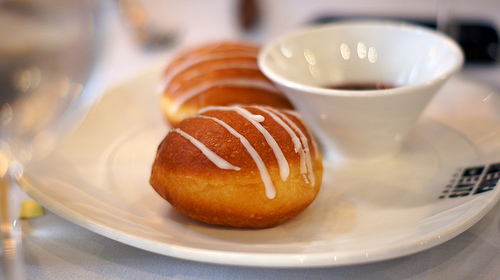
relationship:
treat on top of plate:
[147, 103, 324, 233] [21, 54, 497, 264]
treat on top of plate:
[155, 37, 300, 128] [21, 54, 497, 264]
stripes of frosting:
[164, 103, 319, 202] [168, 124, 244, 176]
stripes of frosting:
[164, 103, 319, 202] [187, 113, 279, 203]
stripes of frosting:
[164, 103, 319, 202] [200, 103, 290, 185]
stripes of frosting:
[164, 103, 319, 202] [245, 100, 317, 190]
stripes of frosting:
[153, 45, 281, 120] [165, 74, 286, 112]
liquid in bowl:
[321, 77, 398, 90] [252, 15, 467, 166]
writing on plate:
[437, 158, 498, 198] [84, 89, 133, 171]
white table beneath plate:
[6, 209, 70, 277] [21, 54, 497, 264]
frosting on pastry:
[167, 99, 319, 200] [143, 101, 328, 231]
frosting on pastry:
[167, 99, 319, 200] [153, 102, 335, 213]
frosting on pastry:
[167, 99, 319, 200] [154, 35, 286, 120]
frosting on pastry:
[157, 49, 321, 201] [143, 101, 328, 231]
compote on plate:
[317, 77, 397, 91] [21, 54, 497, 264]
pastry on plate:
[143, 101, 328, 231] [2, 62, 498, 270]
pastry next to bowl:
[143, 101, 328, 231] [252, 15, 467, 166]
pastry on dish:
[143, 101, 328, 231] [374, 163, 410, 220]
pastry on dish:
[160, 55, 296, 123] [374, 163, 410, 220]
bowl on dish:
[252, 15, 467, 166] [7, 56, 495, 268]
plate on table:
[21, 54, 497, 264] [4, 2, 497, 274]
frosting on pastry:
[167, 99, 319, 200] [160, 48, 294, 124]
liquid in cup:
[321, 77, 398, 90] [255, 18, 467, 163]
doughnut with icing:
[152, 100, 331, 238] [221, 121, 291, 208]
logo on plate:
[441, 159, 499, 199] [21, 54, 497, 264]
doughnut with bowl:
[144, 100, 332, 230] [252, 15, 467, 166]